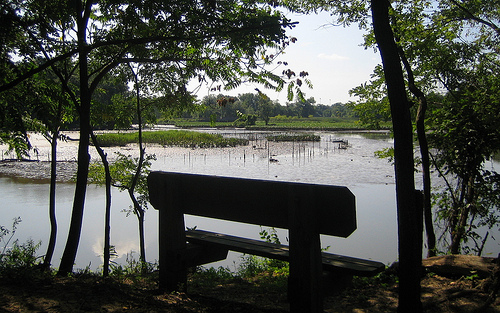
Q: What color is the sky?
A: Light blue.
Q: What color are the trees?
A: Green.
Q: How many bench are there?
A: One.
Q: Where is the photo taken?
A: By the lake.